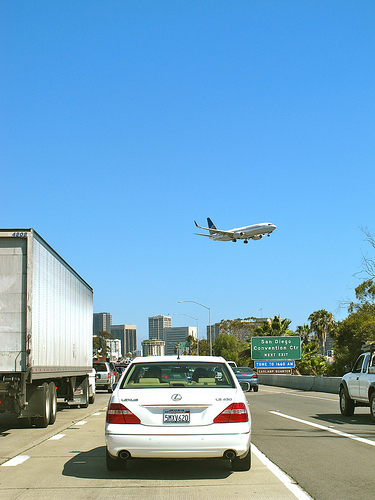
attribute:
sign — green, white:
[249, 333, 302, 362]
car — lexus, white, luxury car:
[102, 354, 251, 477]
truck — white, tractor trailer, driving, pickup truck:
[336, 347, 374, 425]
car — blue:
[228, 365, 262, 392]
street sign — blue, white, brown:
[252, 358, 298, 371]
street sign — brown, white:
[257, 365, 294, 377]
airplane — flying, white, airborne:
[192, 215, 278, 245]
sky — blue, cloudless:
[1, 1, 373, 356]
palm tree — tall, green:
[252, 316, 293, 337]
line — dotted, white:
[4, 408, 107, 473]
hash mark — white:
[2, 451, 34, 469]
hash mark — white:
[47, 427, 68, 443]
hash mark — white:
[75, 417, 89, 429]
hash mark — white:
[90, 410, 105, 419]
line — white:
[268, 408, 373, 452]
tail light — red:
[212, 403, 248, 424]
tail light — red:
[105, 400, 143, 427]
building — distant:
[163, 325, 197, 354]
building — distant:
[148, 314, 171, 341]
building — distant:
[141, 338, 167, 356]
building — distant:
[108, 323, 139, 357]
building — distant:
[94, 309, 114, 338]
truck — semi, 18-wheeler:
[2, 227, 97, 432]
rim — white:
[44, 390, 51, 422]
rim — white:
[52, 395, 57, 418]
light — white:
[106, 408, 136, 416]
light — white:
[221, 409, 249, 416]